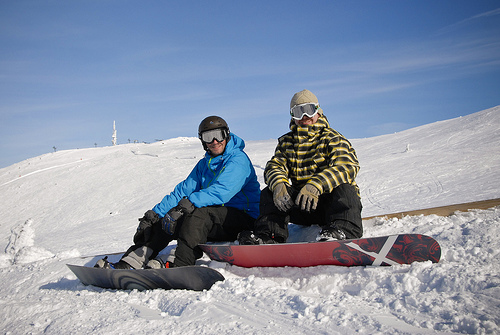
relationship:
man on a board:
[237, 89, 363, 246] [199, 232, 435, 272]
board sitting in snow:
[64, 264, 225, 292] [17, 114, 487, 334]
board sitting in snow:
[198, 233, 441, 269] [17, 114, 487, 334]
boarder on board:
[93, 114, 261, 278] [103, 264, 185, 290]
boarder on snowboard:
[93, 114, 261, 278] [65, 259, 223, 297]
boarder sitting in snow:
[93, 114, 261, 278] [294, 282, 396, 312]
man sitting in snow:
[237, 89, 363, 246] [294, 282, 396, 312]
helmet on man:
[193, 116, 235, 150] [151, 115, 254, 239]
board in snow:
[64, 264, 225, 292] [17, 114, 487, 334]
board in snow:
[198, 233, 441, 269] [17, 114, 487, 334]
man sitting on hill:
[237, 89, 363, 246] [1, 107, 499, 328]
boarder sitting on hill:
[93, 114, 261, 278] [1, 107, 499, 328]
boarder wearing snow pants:
[93, 114, 261, 278] [120, 205, 257, 267]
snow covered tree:
[17, 114, 487, 334] [109, 117, 117, 145]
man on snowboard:
[237, 89, 363, 246] [202, 235, 445, 264]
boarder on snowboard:
[93, 114, 261, 278] [63, 257, 224, 293]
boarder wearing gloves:
[93, 114, 261, 278] [129, 198, 189, 237]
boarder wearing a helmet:
[93, 114, 261, 278] [194, 115, 231, 154]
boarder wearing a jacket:
[93, 114, 261, 278] [154, 133, 271, 222]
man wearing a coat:
[237, 89, 363, 246] [262, 118, 359, 193]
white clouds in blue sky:
[280, 34, 499, 89] [0, 0, 498, 165]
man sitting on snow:
[237, 89, 363, 246] [300, 266, 370, 331]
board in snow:
[64, 264, 225, 292] [221, 270, 486, 334]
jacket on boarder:
[153, 139, 268, 223] [108, 118, 268, 278]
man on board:
[237, 89, 363, 246] [215, 210, 490, 261]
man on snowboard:
[254, 82, 366, 252] [196, 230, 446, 270]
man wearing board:
[237, 89, 363, 246] [64, 264, 225, 292]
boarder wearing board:
[93, 114, 261, 278] [198, 233, 441, 269]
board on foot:
[64, 264, 225, 292] [92, 251, 137, 278]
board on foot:
[64, 264, 225, 292] [142, 255, 187, 288]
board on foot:
[198, 233, 441, 269] [238, 230, 285, 256]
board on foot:
[198, 233, 441, 269] [314, 225, 347, 247]